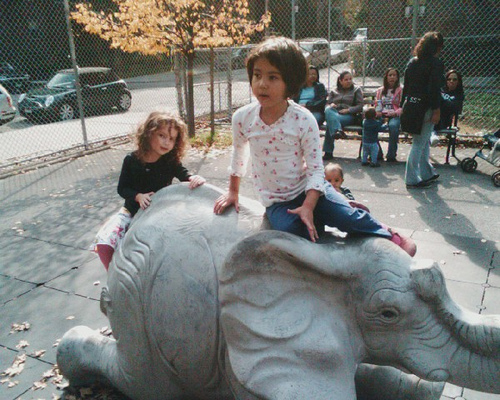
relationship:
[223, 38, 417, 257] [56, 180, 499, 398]
child on elephant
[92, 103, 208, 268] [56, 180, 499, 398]
child on elephant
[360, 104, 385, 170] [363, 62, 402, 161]
toddler in front of sitting women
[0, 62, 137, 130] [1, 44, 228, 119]
two cars parked on road side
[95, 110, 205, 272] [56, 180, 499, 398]
girl playing on elephant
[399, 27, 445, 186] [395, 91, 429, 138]
girl with black bag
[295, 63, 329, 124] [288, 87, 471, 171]
sitting women sitting on bench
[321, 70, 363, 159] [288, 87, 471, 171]
girl sitting on bench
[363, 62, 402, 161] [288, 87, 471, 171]
sitting women sitting on bench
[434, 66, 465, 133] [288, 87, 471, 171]
sitting women sitting on bench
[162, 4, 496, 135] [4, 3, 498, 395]
fence around playground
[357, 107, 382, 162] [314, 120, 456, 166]
child standing by bench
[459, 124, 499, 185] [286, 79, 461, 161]
stroller beside bench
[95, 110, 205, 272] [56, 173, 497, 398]
girl on top of elephant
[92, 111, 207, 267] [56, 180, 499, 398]
child climbing onto elephant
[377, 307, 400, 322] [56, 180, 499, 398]
eye of elephant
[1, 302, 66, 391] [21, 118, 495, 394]
leaves scattered on playground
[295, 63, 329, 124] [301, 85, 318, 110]
sitting women wearing shirt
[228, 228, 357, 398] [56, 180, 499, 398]
ear of elephant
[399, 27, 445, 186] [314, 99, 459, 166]
girl in front of bench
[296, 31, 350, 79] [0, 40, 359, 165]
car parked on street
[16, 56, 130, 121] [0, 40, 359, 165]
car parked on street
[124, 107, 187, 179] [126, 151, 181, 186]
girl wearing black shirt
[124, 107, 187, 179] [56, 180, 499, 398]
girl climbing elephant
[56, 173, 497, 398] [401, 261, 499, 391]
elephant has trunk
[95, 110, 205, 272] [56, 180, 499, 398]
girl sitting on elephant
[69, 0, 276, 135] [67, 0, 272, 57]
tree with leaves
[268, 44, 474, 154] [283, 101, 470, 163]
women sitting on bench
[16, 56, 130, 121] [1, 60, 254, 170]
car parked on street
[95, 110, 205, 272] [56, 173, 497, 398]
girl sits on elephant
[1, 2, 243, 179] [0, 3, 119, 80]
fence surrounds park